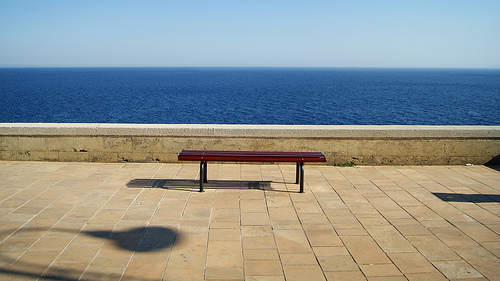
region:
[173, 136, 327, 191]
wooden bench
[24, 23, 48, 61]
white clouds in blue sky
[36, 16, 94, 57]
white clouds in blue sky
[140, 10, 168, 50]
white clouds in blue sky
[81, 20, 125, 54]
white clouds in blue sky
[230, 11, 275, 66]
white clouds in blue sky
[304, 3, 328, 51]
white clouds in blue sky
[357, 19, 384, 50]
white clouds in blue sky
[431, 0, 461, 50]
white clouds in blue sky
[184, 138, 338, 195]
wooden bench at beach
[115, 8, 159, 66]
white clouds in blue sky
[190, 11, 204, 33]
white clouds in blue sky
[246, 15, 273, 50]
white clouds in blue sky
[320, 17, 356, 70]
white clouds in blue sky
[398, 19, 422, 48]
white clouds in blue sky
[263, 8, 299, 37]
white clouds in blue sky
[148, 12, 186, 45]
white clouds in blue sky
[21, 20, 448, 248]
this is along a coast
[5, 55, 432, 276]
this is by a waterfront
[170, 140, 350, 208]
this is a bunch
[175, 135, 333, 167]
the bench is made of metal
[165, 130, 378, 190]
the bench is red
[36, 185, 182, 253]
this is a shadow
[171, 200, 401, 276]
the ground is brick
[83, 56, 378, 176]
this is the ocean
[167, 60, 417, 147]
the ocean is dark blue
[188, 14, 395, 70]
the sky is very light blue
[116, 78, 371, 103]
Blue color sea water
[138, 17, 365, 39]
A blue color sky with clouds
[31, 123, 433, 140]
Concrete wall near the sea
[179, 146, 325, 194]
Wooden bench with steel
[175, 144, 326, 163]
Brown color wood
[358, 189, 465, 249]
Cream color wall tiels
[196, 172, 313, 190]
Black color coated steel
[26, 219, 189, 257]
Shadow of the light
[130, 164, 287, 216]
Shadow of the bench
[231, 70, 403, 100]
Small waves in the sea water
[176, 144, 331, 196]
a red bench on a platform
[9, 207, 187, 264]
shadow of a lamp post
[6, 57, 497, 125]
a vast blue ocean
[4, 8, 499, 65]
a sky with no clouds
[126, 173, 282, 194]
shadow of a bench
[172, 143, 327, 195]
a bench mounted on a stone tile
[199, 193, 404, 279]
stone tiles on the floor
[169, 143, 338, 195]
a red bench with four legs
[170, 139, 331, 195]
a long red bench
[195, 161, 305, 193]
the four supporting legs of a bench